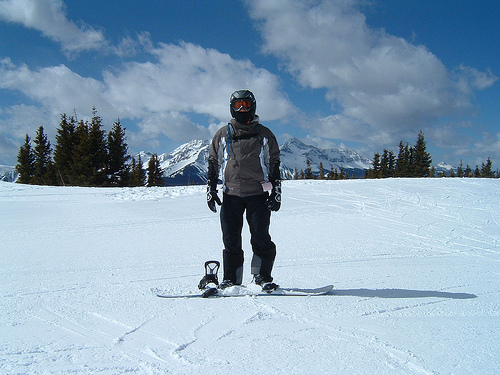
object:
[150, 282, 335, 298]
snowboard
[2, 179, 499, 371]
snow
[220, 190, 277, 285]
ski pants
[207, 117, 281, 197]
ski jacket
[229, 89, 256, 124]
helmet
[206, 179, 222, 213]
glove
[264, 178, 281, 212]
glove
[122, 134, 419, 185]
mountain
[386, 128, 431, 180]
tree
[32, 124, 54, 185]
tree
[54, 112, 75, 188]
tree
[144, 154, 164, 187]
tree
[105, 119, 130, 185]
tree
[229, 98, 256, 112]
goggles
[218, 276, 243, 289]
snowboot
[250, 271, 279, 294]
snowboot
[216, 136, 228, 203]
side stripe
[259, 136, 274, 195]
side stripe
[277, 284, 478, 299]
shadow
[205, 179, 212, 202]
design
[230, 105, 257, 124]
mask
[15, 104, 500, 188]
forest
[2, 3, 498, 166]
sky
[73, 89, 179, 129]
cloud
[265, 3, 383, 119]
cloud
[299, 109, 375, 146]
cloud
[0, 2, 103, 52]
cloud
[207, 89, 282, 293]
man